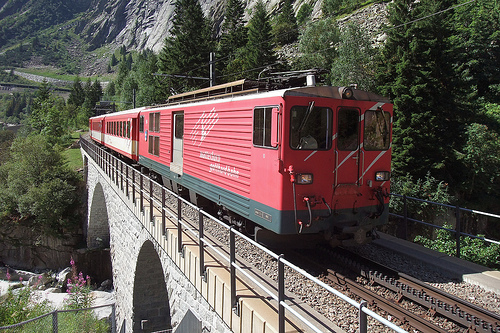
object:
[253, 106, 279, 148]
window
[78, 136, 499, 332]
bridge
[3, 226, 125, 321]
gorge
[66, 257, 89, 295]
flowers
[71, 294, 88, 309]
branches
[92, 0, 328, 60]
mountains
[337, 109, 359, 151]
window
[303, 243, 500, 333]
tracks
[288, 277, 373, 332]
gravel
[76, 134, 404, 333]
railing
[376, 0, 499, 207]
trees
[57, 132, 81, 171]
grass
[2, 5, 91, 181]
valley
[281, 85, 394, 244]
front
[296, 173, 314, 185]
head light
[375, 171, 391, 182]
head light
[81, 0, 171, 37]
hillside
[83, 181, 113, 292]
archway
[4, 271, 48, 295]
flower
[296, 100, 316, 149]
wiper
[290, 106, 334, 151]
windshield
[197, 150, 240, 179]
text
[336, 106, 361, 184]
dor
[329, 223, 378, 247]
bumper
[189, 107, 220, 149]
logo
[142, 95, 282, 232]
side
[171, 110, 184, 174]
door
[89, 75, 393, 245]
car